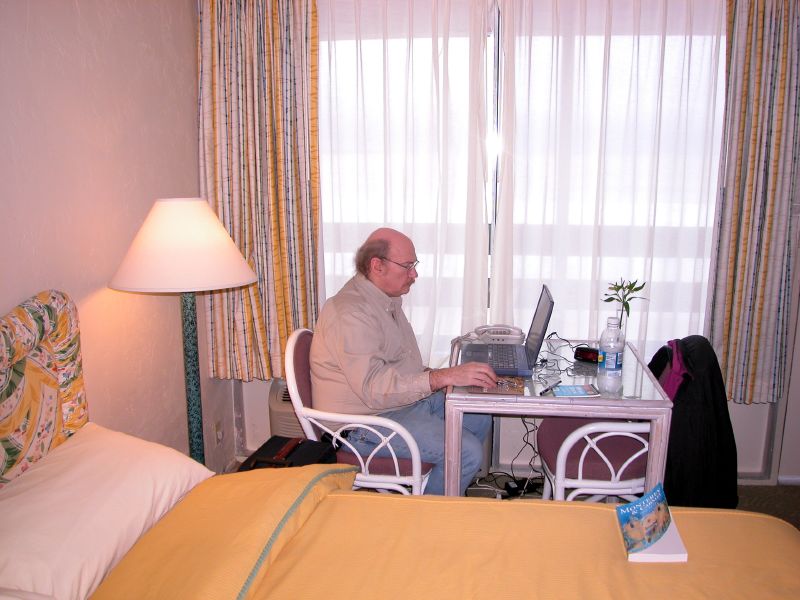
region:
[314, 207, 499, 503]
Man sitting in front of a laptop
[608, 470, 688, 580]
Book on top of the bed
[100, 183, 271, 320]
Lamp shade on the floor lamp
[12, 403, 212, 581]
white pillow on the bed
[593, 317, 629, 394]
water bottle on the table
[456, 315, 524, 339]
phone on the table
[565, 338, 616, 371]
clock on the table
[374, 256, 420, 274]
man wearing reading glasses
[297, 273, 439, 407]
man wearing a brown shirt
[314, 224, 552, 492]
man looking at his laptop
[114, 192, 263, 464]
lamp has white shade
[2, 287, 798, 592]
bed has yellow and blue comforter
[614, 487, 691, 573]
book has blue cover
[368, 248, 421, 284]
man is wearing glasses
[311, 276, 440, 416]
man is wearing a beige shirt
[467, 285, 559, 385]
The laptop is black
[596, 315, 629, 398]
bottle of water is empty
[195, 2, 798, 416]
curtains are white yellow and blue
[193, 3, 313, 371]
Curtain panel on window has yellow, blue, and white colors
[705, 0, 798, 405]
Curtain panel on window has blue, white, and yellow colors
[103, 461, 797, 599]
Yellow comforter on bed in room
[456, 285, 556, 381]
Black laptop on glass table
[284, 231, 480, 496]
Man in bedroom is sitting in a chair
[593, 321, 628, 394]
Plastic water bottle on glass table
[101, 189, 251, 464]
Tall standing lamp with white lampshade near wall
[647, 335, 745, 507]
Black and purple jacket hanging on chair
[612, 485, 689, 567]
Small book laying on the comforter on bed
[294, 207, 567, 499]
A man sitting behind a laptop.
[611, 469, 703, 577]
A book resting on top of a bed.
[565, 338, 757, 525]
A black coat draped over a chair.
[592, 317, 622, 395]
A clear bottle of water with a blue label.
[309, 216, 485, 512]
A man wearing eyeglasses.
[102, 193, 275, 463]
A floor lamp beside the bed.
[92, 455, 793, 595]
A light yellow comforter.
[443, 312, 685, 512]
A glass top table.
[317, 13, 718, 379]
White curtains hanging in the window.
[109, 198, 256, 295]
a white lamp shade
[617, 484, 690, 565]
a partially open book on the bed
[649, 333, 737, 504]
jacket draped over the chair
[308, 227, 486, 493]
man working on the computer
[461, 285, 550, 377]
laptop on the table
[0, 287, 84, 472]
part of yellow, green and white head board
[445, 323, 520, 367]
white phone on the table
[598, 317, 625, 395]
water bottle on the table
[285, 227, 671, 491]
Man sitting at table working on laptop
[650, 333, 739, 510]
Black coat hanging over chair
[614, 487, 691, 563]
Paperback sitting on the bed covers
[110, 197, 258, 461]
Lamp is on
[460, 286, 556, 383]
Laptop on the table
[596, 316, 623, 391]
a plastic water bottle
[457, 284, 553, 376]
an open laptop computer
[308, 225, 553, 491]
a man using a computer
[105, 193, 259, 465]
a green floor lamp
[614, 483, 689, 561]
a trade paperback book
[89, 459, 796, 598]
a yellow bed comforter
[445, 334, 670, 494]
a wood and glass table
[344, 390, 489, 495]
a pair of blue jeans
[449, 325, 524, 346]
a white corded phone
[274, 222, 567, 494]
man using a laptop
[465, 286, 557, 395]
black colored laptop on table